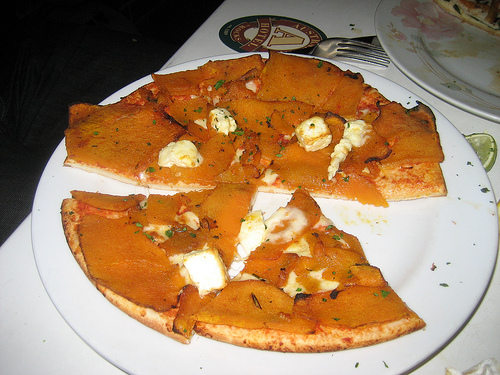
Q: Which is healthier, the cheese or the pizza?
A: The cheese is healthier than the pizza.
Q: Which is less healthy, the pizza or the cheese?
A: The pizza is less healthy than the cheese.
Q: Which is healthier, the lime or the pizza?
A: The lime is healthier than the pizza.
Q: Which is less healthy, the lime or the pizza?
A: The pizza is less healthy than the lime.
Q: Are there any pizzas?
A: Yes, there is a pizza.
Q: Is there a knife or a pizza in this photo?
A: Yes, there is a pizza.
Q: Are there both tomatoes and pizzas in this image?
A: No, there is a pizza but no tomatoes.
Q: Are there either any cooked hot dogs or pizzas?
A: Yes, there is a cooked pizza.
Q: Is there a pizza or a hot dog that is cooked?
A: Yes, the pizza is cooked.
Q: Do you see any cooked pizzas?
A: Yes, there is a cooked pizza.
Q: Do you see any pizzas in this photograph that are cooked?
A: Yes, there is a pizza that is cooked.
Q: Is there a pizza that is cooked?
A: Yes, there is a pizza that is cooked.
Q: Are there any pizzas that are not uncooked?
A: Yes, there is an cooked pizza.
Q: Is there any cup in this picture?
A: No, there are no cups.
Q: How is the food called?
A: The food is a pizza.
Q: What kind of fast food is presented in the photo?
A: The fast food is a pizza.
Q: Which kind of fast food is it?
A: The food is a pizza.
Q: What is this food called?
A: This is a pizza.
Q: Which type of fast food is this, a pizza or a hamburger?
A: This is a pizza.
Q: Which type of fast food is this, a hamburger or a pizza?
A: This is a pizza.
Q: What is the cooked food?
A: The food is a pizza.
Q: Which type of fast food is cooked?
A: The fast food is a pizza.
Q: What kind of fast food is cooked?
A: The fast food is a pizza.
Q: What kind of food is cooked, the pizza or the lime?
A: The pizza is cooked.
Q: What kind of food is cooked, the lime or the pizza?
A: The pizza is cooked.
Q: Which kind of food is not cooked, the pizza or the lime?
A: The lime is not cooked.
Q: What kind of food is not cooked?
A: The food is a lime.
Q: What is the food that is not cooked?
A: The food is a lime.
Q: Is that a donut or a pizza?
A: That is a pizza.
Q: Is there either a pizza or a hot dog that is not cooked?
A: No, there is a pizza but it is cooked.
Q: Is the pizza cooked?
A: Yes, the pizza is cooked.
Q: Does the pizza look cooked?
A: Yes, the pizza is cooked.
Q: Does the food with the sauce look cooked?
A: Yes, the pizza is cooked.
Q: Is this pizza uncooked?
A: No, the pizza is cooked.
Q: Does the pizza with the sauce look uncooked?
A: No, the pizza is cooked.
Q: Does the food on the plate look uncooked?
A: No, the pizza is cooked.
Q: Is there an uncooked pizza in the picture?
A: No, there is a pizza but it is cooked.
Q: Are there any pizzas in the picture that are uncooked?
A: No, there is a pizza but it is cooked.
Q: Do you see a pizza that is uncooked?
A: No, there is a pizza but it is cooked.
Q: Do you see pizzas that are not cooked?
A: No, there is a pizza but it is cooked.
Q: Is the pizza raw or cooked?
A: The pizza is cooked.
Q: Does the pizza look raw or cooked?
A: The pizza is cooked.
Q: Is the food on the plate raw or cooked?
A: The pizza is cooked.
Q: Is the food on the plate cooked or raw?
A: The pizza is cooked.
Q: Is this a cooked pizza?
A: Yes, this is a cooked pizza.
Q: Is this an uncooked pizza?
A: No, this is a cooked pizza.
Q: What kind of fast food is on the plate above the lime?
A: The food is a pizza.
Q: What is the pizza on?
A: The pizza is on the plate.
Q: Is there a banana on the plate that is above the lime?
A: No, there is a pizza on the plate.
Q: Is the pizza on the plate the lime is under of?
A: Yes, the pizza is on the plate.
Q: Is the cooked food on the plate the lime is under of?
A: Yes, the pizza is on the plate.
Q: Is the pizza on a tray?
A: No, the pizza is on the plate.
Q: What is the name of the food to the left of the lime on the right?
A: The food is a pizza.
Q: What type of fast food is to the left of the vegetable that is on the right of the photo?
A: The food is a pizza.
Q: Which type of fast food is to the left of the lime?
A: The food is a pizza.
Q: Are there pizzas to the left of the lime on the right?
A: Yes, there is a pizza to the left of the lime.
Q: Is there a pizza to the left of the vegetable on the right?
A: Yes, there is a pizza to the left of the lime.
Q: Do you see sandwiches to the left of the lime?
A: No, there is a pizza to the left of the lime.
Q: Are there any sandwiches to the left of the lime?
A: No, there is a pizza to the left of the lime.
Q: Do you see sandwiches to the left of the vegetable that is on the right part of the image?
A: No, there is a pizza to the left of the lime.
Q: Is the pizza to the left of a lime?
A: Yes, the pizza is to the left of a lime.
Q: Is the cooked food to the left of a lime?
A: Yes, the pizza is to the left of a lime.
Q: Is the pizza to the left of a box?
A: No, the pizza is to the left of a lime.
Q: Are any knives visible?
A: Yes, there is a knife.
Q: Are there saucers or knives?
A: Yes, there is a knife.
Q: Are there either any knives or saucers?
A: Yes, there is a knife.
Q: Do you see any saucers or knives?
A: Yes, there is a knife.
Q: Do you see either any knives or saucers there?
A: Yes, there is a knife.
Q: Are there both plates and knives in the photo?
A: Yes, there are both a knife and a plate.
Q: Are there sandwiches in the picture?
A: No, there are no sandwiches.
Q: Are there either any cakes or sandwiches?
A: No, there are no sandwiches or cakes.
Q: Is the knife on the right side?
A: Yes, the knife is on the right of the image.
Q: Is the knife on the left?
A: No, the knife is on the right of the image.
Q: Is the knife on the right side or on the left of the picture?
A: The knife is on the right of the image.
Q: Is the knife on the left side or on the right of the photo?
A: The knife is on the right of the image.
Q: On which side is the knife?
A: The knife is on the right of the image.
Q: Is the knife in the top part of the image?
A: Yes, the knife is in the top of the image.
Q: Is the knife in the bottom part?
A: No, the knife is in the top of the image.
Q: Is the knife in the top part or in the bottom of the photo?
A: The knife is in the top of the image.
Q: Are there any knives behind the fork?
A: Yes, there is a knife behind the fork.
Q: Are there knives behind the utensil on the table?
A: Yes, there is a knife behind the fork.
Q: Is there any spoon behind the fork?
A: No, there is a knife behind the fork.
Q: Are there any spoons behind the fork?
A: No, there is a knife behind the fork.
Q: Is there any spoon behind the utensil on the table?
A: No, there is a knife behind the fork.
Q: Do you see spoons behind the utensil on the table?
A: No, there is a knife behind the fork.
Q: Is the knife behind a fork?
A: Yes, the knife is behind a fork.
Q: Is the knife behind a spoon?
A: No, the knife is behind a fork.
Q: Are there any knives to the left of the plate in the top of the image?
A: Yes, there is a knife to the left of the plate.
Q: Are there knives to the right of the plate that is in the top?
A: No, the knife is to the left of the plate.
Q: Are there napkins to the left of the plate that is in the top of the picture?
A: No, there is a knife to the left of the plate.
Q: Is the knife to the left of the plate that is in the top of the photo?
A: Yes, the knife is to the left of the plate.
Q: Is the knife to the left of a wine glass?
A: No, the knife is to the left of the plate.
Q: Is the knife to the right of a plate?
A: No, the knife is to the left of a plate.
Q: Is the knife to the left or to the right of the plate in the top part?
A: The knife is to the left of the plate.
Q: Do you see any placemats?
A: No, there are no placemats.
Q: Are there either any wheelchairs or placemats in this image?
A: No, there are no placemats or wheelchairs.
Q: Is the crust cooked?
A: Yes, the crust is cooked.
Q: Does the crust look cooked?
A: Yes, the crust is cooked.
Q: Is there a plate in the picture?
A: Yes, there is a plate.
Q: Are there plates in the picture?
A: Yes, there is a plate.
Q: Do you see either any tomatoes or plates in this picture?
A: Yes, there is a plate.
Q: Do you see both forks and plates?
A: Yes, there are both a plate and a fork.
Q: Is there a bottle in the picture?
A: No, there are no bottles.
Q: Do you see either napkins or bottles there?
A: No, there are no bottles or napkins.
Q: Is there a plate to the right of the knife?
A: Yes, there is a plate to the right of the knife.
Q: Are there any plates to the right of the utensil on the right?
A: Yes, there is a plate to the right of the knife.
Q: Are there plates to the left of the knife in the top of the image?
A: No, the plate is to the right of the knife.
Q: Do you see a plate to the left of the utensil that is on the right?
A: No, the plate is to the right of the knife.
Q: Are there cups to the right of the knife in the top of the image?
A: No, there is a plate to the right of the knife.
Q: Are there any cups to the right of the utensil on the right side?
A: No, there is a plate to the right of the knife.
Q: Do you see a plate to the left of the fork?
A: No, the plate is to the right of the fork.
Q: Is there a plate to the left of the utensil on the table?
A: No, the plate is to the right of the fork.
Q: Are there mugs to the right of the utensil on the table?
A: No, there is a plate to the right of the fork.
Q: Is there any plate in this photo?
A: Yes, there is a plate.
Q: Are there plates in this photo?
A: Yes, there is a plate.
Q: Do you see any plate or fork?
A: Yes, there is a plate.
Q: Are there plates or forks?
A: Yes, there is a plate.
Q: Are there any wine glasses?
A: No, there are no wine glasses.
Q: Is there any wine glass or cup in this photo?
A: No, there are no wine glasses or cups.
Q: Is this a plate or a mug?
A: This is a plate.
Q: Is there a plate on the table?
A: Yes, there is a plate on the table.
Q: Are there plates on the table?
A: Yes, there is a plate on the table.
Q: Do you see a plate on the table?
A: Yes, there is a plate on the table.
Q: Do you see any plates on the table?
A: Yes, there is a plate on the table.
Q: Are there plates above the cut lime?
A: Yes, there is a plate above the lime.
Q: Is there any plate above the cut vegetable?
A: Yes, there is a plate above the lime.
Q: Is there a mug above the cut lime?
A: No, there is a plate above the lime.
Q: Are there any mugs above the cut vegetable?
A: No, there is a plate above the lime.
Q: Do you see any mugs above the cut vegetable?
A: No, there is a plate above the lime.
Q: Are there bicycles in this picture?
A: No, there are no bicycles.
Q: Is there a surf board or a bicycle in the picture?
A: No, there are no bicycles or surfboards.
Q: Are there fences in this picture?
A: No, there are no fences.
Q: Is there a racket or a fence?
A: No, there are no fences or rackets.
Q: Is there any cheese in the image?
A: Yes, there is cheese.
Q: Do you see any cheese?
A: Yes, there is cheese.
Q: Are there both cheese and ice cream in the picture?
A: No, there is cheese but no ice cream.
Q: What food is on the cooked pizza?
A: The food is cheese.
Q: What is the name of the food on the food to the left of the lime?
A: The food is cheese.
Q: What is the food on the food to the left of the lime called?
A: The food is cheese.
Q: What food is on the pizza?
A: The food is cheese.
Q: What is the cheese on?
A: The cheese is on the pizza.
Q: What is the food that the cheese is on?
A: The food is a pizza.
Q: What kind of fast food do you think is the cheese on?
A: The cheese is on the pizza.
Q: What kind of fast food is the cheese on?
A: The cheese is on the pizza.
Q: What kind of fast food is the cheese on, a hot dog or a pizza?
A: The cheese is on a pizza.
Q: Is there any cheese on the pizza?
A: Yes, there is cheese on the pizza.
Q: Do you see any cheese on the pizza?
A: Yes, there is cheese on the pizza.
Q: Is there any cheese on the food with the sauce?
A: Yes, there is cheese on the pizza.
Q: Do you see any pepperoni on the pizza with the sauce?
A: No, there is cheese on the pizza.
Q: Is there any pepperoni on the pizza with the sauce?
A: No, there is cheese on the pizza.